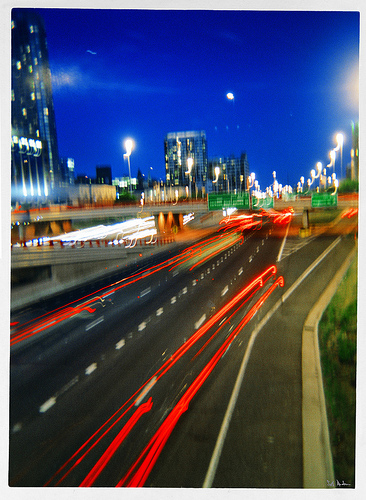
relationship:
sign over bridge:
[202, 188, 251, 209] [18, 202, 359, 242]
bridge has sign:
[18, 202, 359, 242] [202, 188, 251, 209]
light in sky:
[8, 9, 359, 489] [47, 30, 161, 162]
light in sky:
[8, 9, 359, 489] [43, 5, 341, 132]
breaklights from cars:
[152, 329, 224, 426] [275, 271, 288, 290]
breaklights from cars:
[152, 329, 224, 426] [268, 261, 277, 274]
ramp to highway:
[10, 233, 180, 310] [8, 194, 360, 490]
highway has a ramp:
[8, 194, 360, 490] [10, 233, 180, 310]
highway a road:
[17, 214, 360, 492] [109, 271, 299, 485]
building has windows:
[165, 133, 211, 194] [12, 57, 44, 132]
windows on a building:
[12, 57, 44, 132] [165, 133, 211, 194]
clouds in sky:
[45, 9, 360, 190] [43, 5, 341, 132]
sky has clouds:
[42, 11, 360, 193] [43, 61, 101, 99]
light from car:
[117, 275, 285, 491] [265, 259, 278, 277]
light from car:
[117, 275, 285, 491] [274, 268, 288, 286]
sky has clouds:
[42, 11, 360, 193] [50, 71, 171, 96]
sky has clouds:
[42, 11, 360, 193] [73, 73, 149, 96]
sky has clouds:
[53, 11, 349, 116] [48, 61, 109, 106]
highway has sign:
[8, 194, 360, 490] [307, 187, 339, 212]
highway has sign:
[8, 194, 360, 490] [254, 192, 278, 211]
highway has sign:
[8, 194, 360, 490] [204, 188, 254, 212]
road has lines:
[60, 210, 364, 477] [47, 284, 156, 415]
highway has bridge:
[8, 194, 360, 490] [12, 194, 364, 245]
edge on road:
[299, 241, 356, 488] [12, 219, 306, 488]